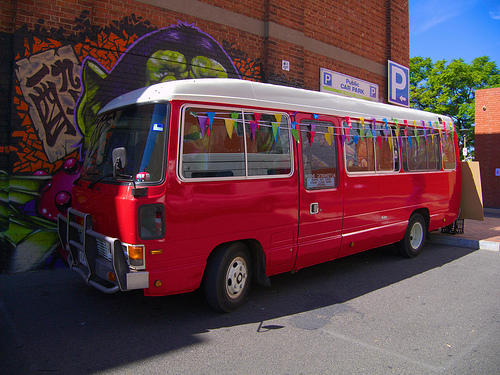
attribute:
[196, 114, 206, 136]
flag — multi-colored, triangular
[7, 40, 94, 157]
writing — asian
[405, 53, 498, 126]
tree — Bright and green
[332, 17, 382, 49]
bricks — orange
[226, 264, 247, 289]
rim — white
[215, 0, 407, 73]
bricks — red 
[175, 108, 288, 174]
windows — row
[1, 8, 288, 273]
grafitti — multi-colored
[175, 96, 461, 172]
flags — colorful 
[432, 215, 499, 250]
sidewalk — pink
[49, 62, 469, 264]
bus — no moving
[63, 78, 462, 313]
minivan — parked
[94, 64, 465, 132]
top — white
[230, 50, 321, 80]
building — brick